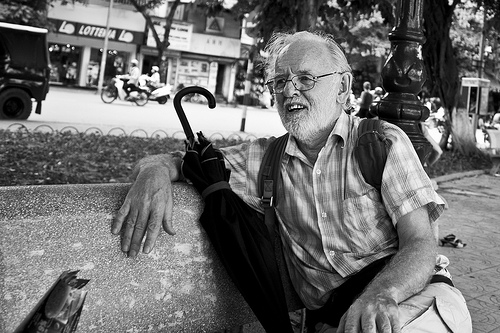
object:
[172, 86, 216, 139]
handle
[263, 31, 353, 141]
head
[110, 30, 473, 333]
man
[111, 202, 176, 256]
fingers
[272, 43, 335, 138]
face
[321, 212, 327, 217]
buttons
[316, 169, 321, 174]
buttons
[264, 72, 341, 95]
glasses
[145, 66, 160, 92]
people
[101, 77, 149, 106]
bikes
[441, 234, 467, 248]
birds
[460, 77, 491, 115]
booth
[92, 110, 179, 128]
sidewalk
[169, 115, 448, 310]
shirt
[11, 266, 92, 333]
bag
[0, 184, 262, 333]
bench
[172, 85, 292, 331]
umbrella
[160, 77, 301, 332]
umbrella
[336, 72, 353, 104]
ear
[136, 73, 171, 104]
motorcyclist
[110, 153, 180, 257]
hand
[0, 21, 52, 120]
jeep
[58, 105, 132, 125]
road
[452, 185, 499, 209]
sidewalk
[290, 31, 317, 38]
hair